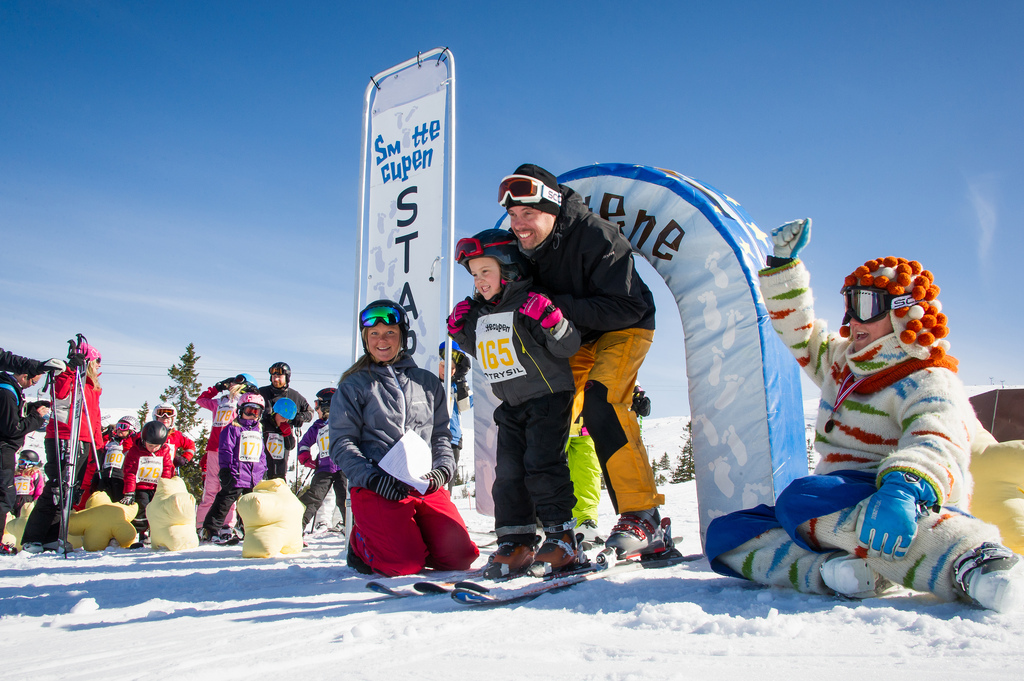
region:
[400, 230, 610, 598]
Little girl on ski's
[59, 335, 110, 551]
Camera is on a tripod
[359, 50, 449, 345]
Sign for the competition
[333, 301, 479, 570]
Woman on the ground is a race official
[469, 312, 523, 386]
Girl wearing participant ID number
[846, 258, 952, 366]
Woman wearing strange hat with orange balls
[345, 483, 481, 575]
Woman wearing pink snowboard pants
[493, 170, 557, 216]
white goggles on head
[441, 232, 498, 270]
red goggles on head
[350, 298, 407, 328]
green goggles on head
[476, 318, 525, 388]
white sign on skiier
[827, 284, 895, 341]
goggles on person's face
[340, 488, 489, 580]
red pants on the person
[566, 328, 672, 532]
yellow pants on person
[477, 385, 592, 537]
black pants on person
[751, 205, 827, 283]
the person's right hand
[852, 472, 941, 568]
the person's left hand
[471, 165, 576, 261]
the head of an adult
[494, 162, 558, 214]
the goggle of an adult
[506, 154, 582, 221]
the hat of an adult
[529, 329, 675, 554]
the pants of an adult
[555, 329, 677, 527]
the leg of an adult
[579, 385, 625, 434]
the knee of an adult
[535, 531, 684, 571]
the feet of an adult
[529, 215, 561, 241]
the cheek of an adult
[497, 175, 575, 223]
the glasses are white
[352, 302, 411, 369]
the lady is smiling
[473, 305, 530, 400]
the number is on the jacket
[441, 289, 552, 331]
the gloves are pink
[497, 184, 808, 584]
the arch is behind man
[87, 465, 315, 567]
the figures are in the snow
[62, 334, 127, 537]
the camera is on tripod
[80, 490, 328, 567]
figures in the snow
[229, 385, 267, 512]
a person standing on the snow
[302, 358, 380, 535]
a person standing on the snow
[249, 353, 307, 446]
a person standing on the snow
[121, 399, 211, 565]
a person standing on the snow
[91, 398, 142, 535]
a person standing on the snow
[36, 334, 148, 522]
a person standing on the snow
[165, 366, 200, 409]
green leaves on the tree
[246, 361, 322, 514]
A person is standing up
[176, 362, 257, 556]
A person is standing up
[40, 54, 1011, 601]
a bright blue sky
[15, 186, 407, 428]
clouds in the sky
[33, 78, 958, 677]
snow in the background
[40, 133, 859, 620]
people playing in the snow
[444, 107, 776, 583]
man holding a child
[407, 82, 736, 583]
man wearing a black sweater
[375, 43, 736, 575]
man wearing googles in the background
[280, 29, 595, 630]
sign on the snow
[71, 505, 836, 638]
shadows on the snow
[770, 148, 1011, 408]
person wearing a red hat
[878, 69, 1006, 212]
Large body of blue skies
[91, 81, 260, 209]
Large body of blue skies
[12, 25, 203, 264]
Large body of blue skies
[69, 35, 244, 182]
Large body of blue skies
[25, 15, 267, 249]
Large body of blue skies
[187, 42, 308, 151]
Large body of blue skies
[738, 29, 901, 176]
Large body of blue skies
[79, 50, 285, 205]
Large body of blue skies